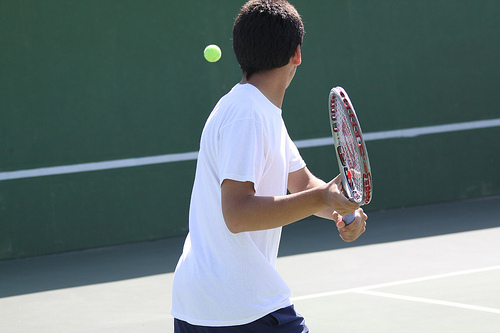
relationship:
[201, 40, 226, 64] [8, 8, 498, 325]
tennis ball in air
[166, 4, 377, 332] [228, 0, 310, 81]
person has head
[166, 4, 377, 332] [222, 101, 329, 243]
person has arm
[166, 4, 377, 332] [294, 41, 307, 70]
person has ear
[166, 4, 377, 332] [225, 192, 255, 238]
person has elbow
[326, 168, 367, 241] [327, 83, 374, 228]
hands holding racket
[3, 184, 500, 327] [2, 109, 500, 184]
tennis field has line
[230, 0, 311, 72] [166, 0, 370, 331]
hair on man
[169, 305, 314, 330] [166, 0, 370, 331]
shorts on man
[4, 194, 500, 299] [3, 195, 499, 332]
shadow on ground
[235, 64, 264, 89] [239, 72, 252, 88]
neck has hair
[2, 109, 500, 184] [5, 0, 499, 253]
line on wall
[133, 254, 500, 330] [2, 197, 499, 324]
lines on court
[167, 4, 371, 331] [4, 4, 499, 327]
tennis player playing tennis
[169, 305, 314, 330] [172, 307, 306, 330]
shorts have pocket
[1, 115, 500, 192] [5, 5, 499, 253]
stripe on background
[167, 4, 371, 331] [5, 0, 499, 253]
tennis player playing on wall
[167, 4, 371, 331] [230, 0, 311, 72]
tennis player with hair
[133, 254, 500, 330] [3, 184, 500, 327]
lines on tennis field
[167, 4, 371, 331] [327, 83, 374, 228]
tennis player holding racket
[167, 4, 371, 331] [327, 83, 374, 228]
tennis player swinging racket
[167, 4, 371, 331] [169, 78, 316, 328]
tennis player wearing tee shirt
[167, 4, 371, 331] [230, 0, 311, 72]
tennis player has hair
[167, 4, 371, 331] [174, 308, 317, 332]
tennis player wearing blue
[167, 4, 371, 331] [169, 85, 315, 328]
tennis player wearing white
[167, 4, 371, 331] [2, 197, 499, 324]
tennis player standing on court